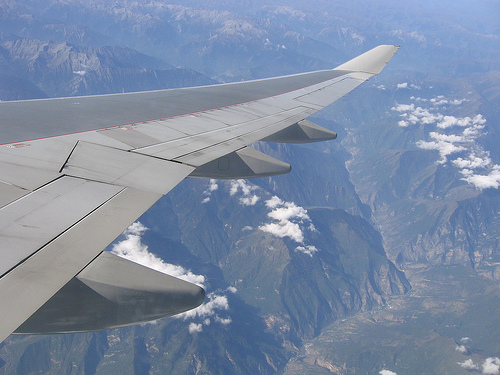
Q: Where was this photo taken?
A: In air.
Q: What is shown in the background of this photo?
A: Mountains.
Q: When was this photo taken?
A: Daytime.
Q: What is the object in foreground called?
A: Airplane wing.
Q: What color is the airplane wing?
A: Gray.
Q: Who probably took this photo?
A: Passenger on plane.